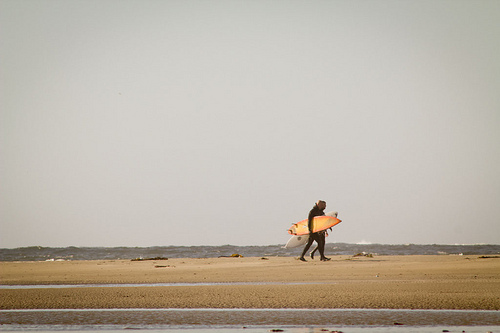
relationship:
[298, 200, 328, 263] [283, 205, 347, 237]
man carrying a surfboard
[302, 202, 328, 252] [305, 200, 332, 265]
wet suit on man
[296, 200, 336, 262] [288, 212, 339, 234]
man holding surfboard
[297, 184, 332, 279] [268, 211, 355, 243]
people carrying surfboards